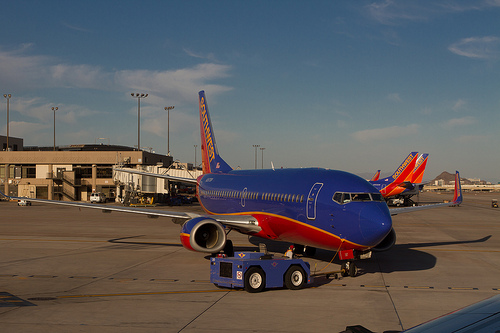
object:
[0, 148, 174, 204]
building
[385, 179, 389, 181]
american flag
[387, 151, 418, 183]
plane's tail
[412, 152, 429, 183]
plane's tail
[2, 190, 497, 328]
ground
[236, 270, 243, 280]
sign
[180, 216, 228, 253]
engine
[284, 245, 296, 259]
man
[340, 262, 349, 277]
wheels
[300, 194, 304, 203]
windows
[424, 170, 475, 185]
brown mountain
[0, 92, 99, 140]
cloud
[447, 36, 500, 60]
cloud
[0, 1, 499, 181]
sky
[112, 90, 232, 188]
tail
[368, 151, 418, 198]
airplane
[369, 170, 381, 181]
airplane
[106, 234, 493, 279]
shadow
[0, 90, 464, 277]
plane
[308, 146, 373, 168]
white cloud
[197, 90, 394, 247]
blue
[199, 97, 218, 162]
orange letters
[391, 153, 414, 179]
orange letters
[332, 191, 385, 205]
windshield area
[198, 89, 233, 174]
tail wing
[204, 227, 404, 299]
towing airplane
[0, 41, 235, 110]
clouds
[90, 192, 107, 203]
white van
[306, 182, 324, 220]
door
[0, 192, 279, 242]
wings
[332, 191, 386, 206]
windshield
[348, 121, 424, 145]
cloud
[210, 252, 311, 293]
vehicle